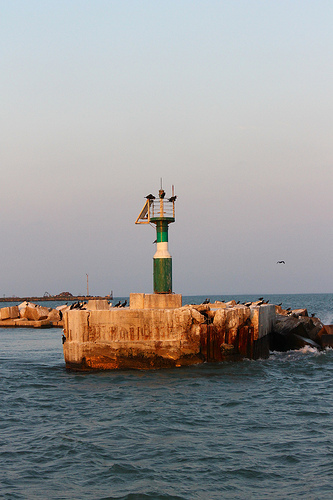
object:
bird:
[113, 300, 122, 309]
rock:
[74, 313, 212, 372]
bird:
[200, 297, 208, 304]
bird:
[293, 311, 303, 316]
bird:
[70, 300, 80, 308]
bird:
[240, 299, 247, 305]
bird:
[276, 260, 286, 264]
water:
[11, 378, 323, 494]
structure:
[154, 224, 179, 296]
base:
[133, 294, 181, 310]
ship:
[3, 292, 116, 301]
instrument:
[137, 204, 151, 222]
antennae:
[159, 178, 167, 191]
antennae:
[172, 183, 179, 194]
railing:
[149, 204, 179, 218]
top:
[159, 224, 165, 230]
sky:
[0, 0, 333, 297]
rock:
[4, 300, 61, 329]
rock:
[271, 316, 324, 351]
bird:
[58, 310, 63, 321]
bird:
[16, 305, 19, 307]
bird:
[145, 194, 153, 199]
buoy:
[134, 177, 177, 292]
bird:
[159, 192, 166, 199]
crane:
[85, 268, 95, 297]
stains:
[81, 349, 232, 368]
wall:
[79, 317, 266, 363]